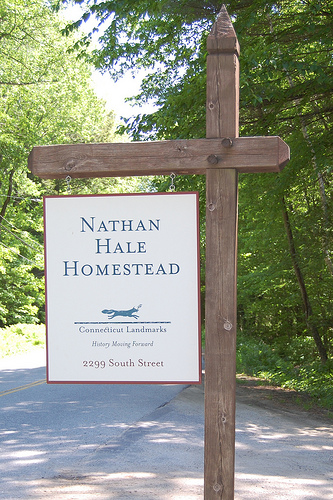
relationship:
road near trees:
[13, 338, 276, 499] [0, 4, 326, 387]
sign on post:
[38, 193, 206, 388] [189, 5, 259, 499]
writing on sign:
[53, 212, 188, 374] [38, 193, 206, 388]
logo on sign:
[71, 303, 172, 326] [38, 193, 206, 388]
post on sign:
[189, 5, 259, 499] [38, 193, 206, 388]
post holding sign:
[189, 5, 259, 499] [38, 193, 206, 388]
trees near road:
[0, 4, 326, 387] [13, 338, 276, 499]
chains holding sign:
[50, 176, 190, 191] [38, 193, 206, 388]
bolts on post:
[204, 136, 240, 168] [189, 5, 259, 499]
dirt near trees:
[247, 373, 313, 414] [0, 4, 326, 387]